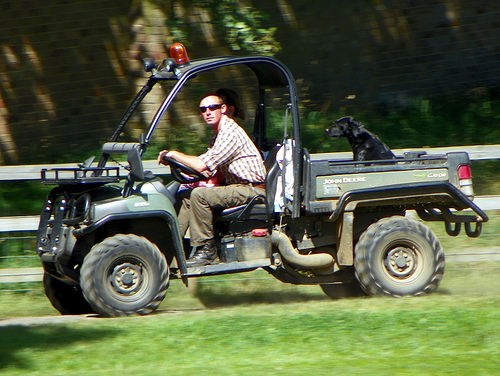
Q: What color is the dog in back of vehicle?
A: Black.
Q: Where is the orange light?
A: On top of vehicle.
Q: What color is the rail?
A: Silver.